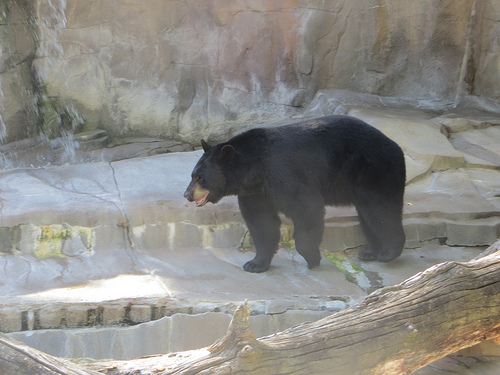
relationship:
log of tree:
[144, 254, 483, 364] [212, 300, 392, 366]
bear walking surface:
[182, 115, 406, 273] [164, 270, 367, 302]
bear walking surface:
[182, 115, 406, 273] [147, 254, 249, 304]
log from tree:
[0, 254, 483, 375] [11, 231, 484, 364]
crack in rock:
[2, 3, 50, 122] [25, 11, 217, 148]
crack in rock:
[2, 3, 50, 122] [51, 8, 289, 117]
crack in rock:
[2, 3, 50, 122] [55, 18, 300, 97]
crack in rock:
[2, 3, 50, 122] [31, 6, 256, 124]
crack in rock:
[2, 3, 50, 122] [27, 4, 226, 123]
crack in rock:
[26, 8, 308, 120] [12, 4, 85, 136]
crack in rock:
[2, 3, 50, 122] [27, 10, 361, 119]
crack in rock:
[2, 3, 50, 122] [33, 6, 413, 120]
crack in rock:
[21, 7, 46, 115] [37, 0, 450, 116]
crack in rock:
[2, 3, 50, 122] [40, 8, 451, 124]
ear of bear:
[196, 134, 240, 174] [181, 112, 418, 266]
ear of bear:
[197, 130, 252, 165] [181, 112, 418, 266]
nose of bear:
[181, 179, 204, 207] [181, 112, 418, 266]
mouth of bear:
[183, 180, 213, 214] [182, 115, 406, 273]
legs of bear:
[226, 200, 324, 280] [181, 112, 418, 266]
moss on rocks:
[42, 104, 188, 177] [1, 100, 320, 351]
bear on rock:
[169, 129, 439, 280] [47, 139, 390, 373]